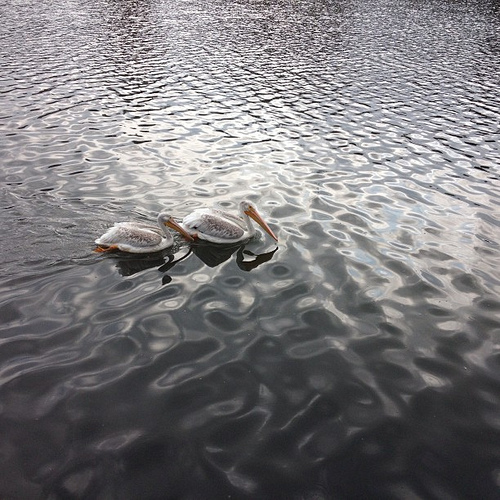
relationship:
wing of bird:
[95, 222, 163, 247] [93, 210, 193, 252]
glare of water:
[119, 122, 319, 207] [0, 1, 500, 498]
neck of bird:
[242, 214, 252, 235] [180, 200, 277, 245]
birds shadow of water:
[124, 236, 270, 303] [24, 23, 484, 473]